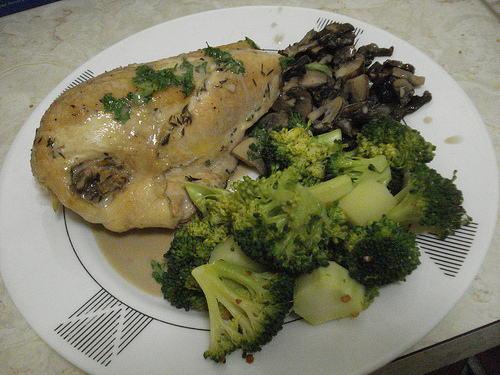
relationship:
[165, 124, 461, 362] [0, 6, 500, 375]
broccoli on plate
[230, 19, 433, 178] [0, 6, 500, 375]
mushrooms on plate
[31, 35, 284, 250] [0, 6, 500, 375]
chicken on plate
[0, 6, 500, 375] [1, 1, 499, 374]
plate on counter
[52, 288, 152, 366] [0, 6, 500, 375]
design on plate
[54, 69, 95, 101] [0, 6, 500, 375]
design on plate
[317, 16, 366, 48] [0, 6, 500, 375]
design on plate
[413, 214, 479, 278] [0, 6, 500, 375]
design on plate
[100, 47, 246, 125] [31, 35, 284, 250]
garnish on chicken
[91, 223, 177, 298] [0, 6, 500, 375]
gravy on plate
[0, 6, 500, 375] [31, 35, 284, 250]
plate of chicken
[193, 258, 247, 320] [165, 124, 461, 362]
stem part of broccoli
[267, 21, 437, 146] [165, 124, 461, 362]
mushrooms and broccoli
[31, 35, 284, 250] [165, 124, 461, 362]
chicken with broccoli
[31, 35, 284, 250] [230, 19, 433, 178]
chicken with mushrooms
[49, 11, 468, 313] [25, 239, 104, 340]
dinner served on plate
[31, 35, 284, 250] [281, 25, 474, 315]
chicken served  with vegetables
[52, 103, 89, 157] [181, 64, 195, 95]
skin covered with coriander leaves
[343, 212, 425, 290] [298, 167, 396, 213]
floret next to stalks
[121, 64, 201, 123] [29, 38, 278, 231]
leaves on top of chicken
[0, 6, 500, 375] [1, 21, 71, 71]
plate kept on table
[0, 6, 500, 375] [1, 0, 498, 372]
plate kept in table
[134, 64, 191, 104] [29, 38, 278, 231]
coriander leaves on top of chicken